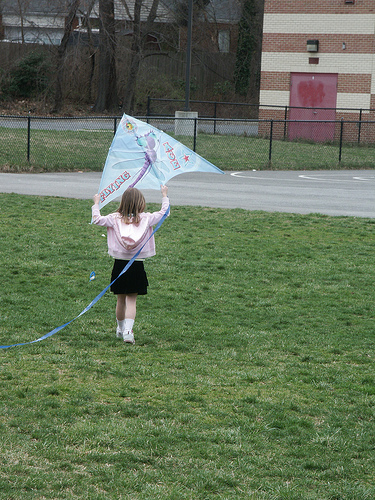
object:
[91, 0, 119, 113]
trees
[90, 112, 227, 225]
kite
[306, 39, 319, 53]
light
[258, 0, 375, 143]
wall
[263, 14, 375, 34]
white building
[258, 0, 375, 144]
brick building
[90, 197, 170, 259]
jacket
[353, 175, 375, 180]
circles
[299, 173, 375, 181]
circles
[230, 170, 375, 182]
circles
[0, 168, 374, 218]
asphalt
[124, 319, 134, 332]
sock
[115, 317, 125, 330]
sock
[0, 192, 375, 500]
grass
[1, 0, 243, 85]
building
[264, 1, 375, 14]
brick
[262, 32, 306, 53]
brick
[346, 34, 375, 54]
brick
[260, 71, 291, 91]
brick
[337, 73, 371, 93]
brick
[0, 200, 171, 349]
tail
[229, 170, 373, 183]
lines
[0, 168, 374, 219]
basketball court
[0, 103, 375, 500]
ground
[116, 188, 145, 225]
hair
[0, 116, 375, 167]
fence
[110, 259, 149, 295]
skirt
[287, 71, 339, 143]
door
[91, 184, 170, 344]
girl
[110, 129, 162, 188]
dragonfly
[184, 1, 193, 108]
pole